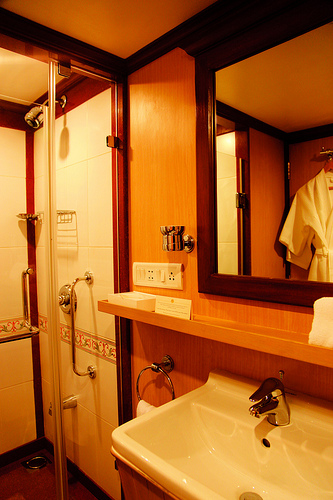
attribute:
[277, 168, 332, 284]
robe — white, hanging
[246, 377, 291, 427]
faucet — chrome, silver, metal, shiny, steel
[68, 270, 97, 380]
handle — stainless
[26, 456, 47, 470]
drain — stainless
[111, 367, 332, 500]
sink — white, porcelain, reflecting, ceramic, shiny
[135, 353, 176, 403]
towel holder — stainless, silver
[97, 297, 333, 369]
shelf — wood, light brown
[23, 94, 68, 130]
shower head — silver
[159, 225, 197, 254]
light — silver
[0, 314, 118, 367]
tile — decorative